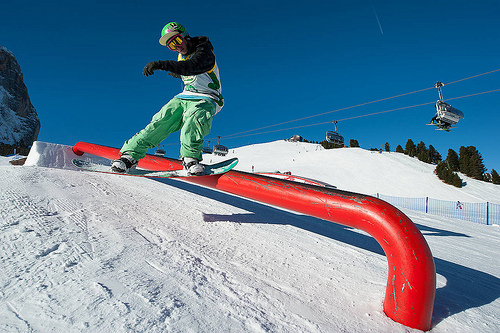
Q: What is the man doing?
A: Snowboarding.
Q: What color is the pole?
A: Red.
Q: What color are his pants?
A: Green.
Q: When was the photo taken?
A: Afternoon.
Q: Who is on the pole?
A: A snowboarder.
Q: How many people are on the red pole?
A: One.